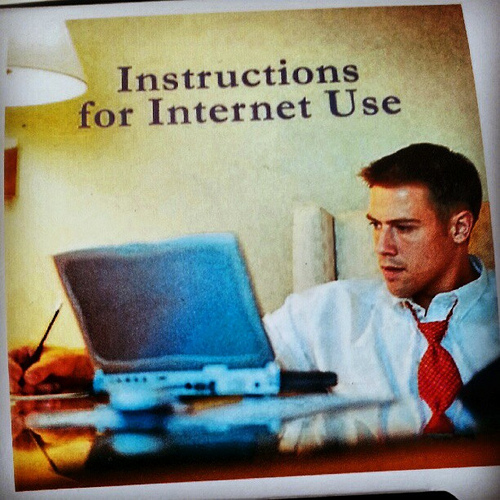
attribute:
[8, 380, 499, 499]
table top — brown table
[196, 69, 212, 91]
lettering — Black 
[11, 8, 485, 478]
advertisement —   internet use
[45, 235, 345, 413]
laptop —  open 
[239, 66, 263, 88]
lettering — Black 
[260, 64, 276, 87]
lettering — Black 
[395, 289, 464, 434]
necktie — red neck 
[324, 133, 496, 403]
man —  sitting down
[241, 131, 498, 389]
man — sitting down 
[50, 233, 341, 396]
laptop — gray, open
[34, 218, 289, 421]
laptop — open 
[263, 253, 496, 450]
shirt — white dress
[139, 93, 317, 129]
internet — Poster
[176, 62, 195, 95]
lettering — Black 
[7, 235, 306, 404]
computer — Grey 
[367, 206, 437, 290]
face — man's 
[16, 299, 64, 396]
pen — black ink 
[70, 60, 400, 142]
lettering — Black 